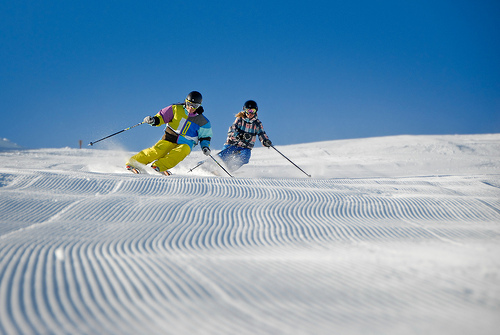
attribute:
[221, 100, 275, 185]
person — skiing, leaning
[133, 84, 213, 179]
person — skiing, leaning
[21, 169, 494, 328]
snow — present, white, powdery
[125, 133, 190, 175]
snow pants — yellow, bright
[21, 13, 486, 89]
sky — blue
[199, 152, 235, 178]
pole — thin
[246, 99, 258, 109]
hat — black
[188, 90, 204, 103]
hat — black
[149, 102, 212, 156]
jacket — multicolored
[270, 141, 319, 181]
pole — thin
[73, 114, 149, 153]
pole — thin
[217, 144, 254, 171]
pants — blue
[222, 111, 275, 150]
jacket — plaid, blue, yellow, pink